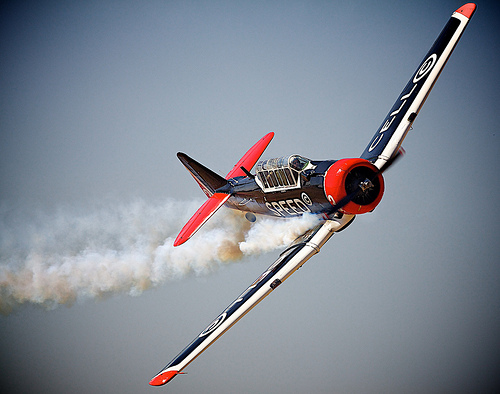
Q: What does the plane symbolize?
A: Patriotism.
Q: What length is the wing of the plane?
A: Long.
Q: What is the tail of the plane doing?
A: Pointed.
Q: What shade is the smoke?
A: Gray.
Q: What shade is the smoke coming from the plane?
A: White.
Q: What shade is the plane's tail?
A: Red.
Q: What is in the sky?
A: An airplane.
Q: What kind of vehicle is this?
A: Airplane.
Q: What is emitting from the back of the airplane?
A: Smoke.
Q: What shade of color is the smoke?
A: White.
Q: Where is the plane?
A: In mid air.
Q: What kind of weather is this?
A: Clear with no clouds.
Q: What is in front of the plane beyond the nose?
A: Propeller.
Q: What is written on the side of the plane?
A: Speed.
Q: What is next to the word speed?
A: Copyright symbol.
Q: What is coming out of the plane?
A: Smoke.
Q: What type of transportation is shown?
A: Plane.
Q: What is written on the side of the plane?
A: Speed.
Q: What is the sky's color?
A: Grey.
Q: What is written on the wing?
A: Cell.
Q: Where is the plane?
A: In the air.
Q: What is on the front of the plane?
A: Propeller.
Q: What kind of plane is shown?
A: Jet.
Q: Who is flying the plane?
A: Pilot.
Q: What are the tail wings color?
A: Red.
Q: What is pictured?
A: An airplane.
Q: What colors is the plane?
A: Blue, red, and white.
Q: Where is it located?
A: In the sky.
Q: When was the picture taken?
A: Daylight.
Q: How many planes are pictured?
A: 1.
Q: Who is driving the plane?
A: A pilot.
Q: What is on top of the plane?
A: Windows.